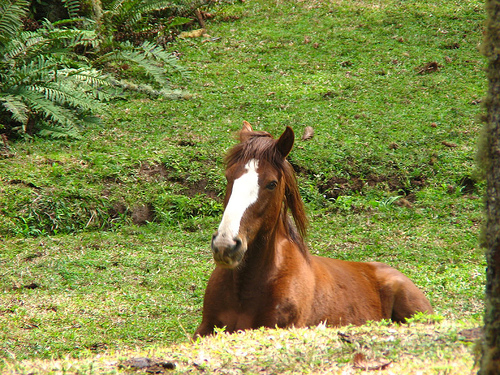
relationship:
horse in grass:
[191, 117, 433, 339] [52, 278, 174, 365]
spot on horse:
[210, 154, 259, 257] [191, 117, 433, 339]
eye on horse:
[265, 181, 277, 191] [93, 92, 467, 373]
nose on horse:
[209, 190, 272, 272] [191, 117, 433, 339]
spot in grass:
[348, 108, 439, 206] [367, 87, 489, 209]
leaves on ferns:
[34, 77, 95, 104] [0, 0, 188, 141]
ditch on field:
[85, 257, 494, 366] [0, 0, 497, 373]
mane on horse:
[246, 140, 346, 194] [246, 144, 373, 286]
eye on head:
[258, 178, 280, 195] [203, 105, 280, 275]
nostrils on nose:
[208, 232, 249, 259] [207, 227, 251, 269]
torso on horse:
[288, 226, 387, 328] [191, 117, 433, 339]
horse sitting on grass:
[191, 117, 433, 339] [2, 4, 491, 372]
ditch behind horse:
[1, 146, 484, 240] [191, 117, 433, 339]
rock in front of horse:
[117, 353, 179, 371] [191, 117, 433, 339]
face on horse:
[213, 130, 280, 267] [191, 117, 433, 339]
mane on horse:
[238, 130, 315, 250] [191, 117, 433, 339]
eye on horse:
[265, 181, 277, 191] [191, 117, 433, 339]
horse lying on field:
[191, 117, 433, 339] [4, 4, 497, 373]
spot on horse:
[210, 154, 259, 257] [193, 108, 448, 348]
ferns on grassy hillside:
[0, 0, 203, 141] [0, 2, 500, 185]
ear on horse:
[273, 124, 292, 154] [196, 121, 428, 338]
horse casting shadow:
[191, 117, 433, 339] [192, 316, 492, 374]